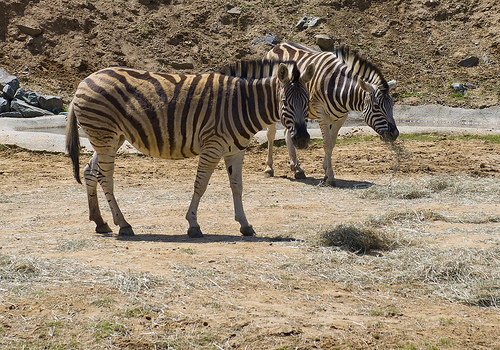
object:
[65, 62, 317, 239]
zebra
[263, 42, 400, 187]
zebra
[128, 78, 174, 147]
strips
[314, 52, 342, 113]
strips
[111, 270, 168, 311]
dead grass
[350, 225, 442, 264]
dead grass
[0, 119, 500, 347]
ground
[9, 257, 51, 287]
dead grass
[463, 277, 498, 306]
grass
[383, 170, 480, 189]
grass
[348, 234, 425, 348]
grass